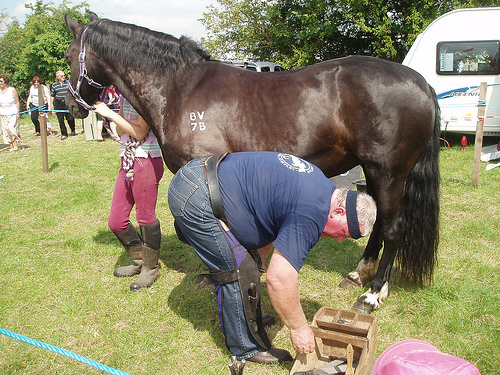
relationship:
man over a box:
[169, 150, 378, 365] [292, 305, 379, 374]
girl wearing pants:
[91, 90, 166, 290] [109, 154, 165, 232]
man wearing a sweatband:
[169, 150, 378, 365] [345, 189, 362, 241]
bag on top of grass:
[375, 341, 484, 374] [1, 112, 499, 374]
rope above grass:
[435, 82, 499, 107] [1, 112, 499, 374]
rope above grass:
[0, 105, 72, 116] [1, 112, 499, 374]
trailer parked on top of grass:
[394, 8, 500, 143] [1, 112, 499, 374]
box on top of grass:
[292, 305, 379, 374] [1, 112, 499, 374]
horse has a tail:
[64, 9, 442, 312] [391, 83, 439, 290]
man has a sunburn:
[169, 150, 378, 365] [320, 218, 365, 242]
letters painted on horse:
[188, 110, 209, 134] [64, 9, 442, 312]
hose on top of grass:
[0, 324, 133, 374] [1, 112, 499, 374]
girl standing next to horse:
[91, 90, 166, 290] [64, 9, 442, 312]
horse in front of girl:
[64, 9, 442, 312] [91, 90, 166, 290]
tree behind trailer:
[196, 1, 499, 73] [394, 8, 500, 143]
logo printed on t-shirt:
[277, 150, 314, 174] [219, 150, 335, 272]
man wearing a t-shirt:
[169, 150, 378, 365] [219, 150, 335, 272]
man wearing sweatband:
[169, 150, 378, 365] [345, 189, 362, 241]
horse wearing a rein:
[64, 9, 442, 312] [65, 21, 106, 115]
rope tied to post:
[435, 82, 499, 107] [473, 79, 489, 188]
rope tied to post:
[0, 105, 72, 116] [37, 83, 53, 173]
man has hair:
[169, 150, 378, 365] [338, 187, 377, 238]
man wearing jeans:
[169, 150, 378, 365] [166, 157, 267, 360]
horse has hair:
[64, 9, 442, 312] [78, 19, 208, 77]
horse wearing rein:
[64, 9, 442, 312] [65, 21, 106, 115]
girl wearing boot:
[91, 90, 166, 290] [112, 222, 146, 278]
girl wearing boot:
[91, 90, 166, 290] [128, 218, 161, 297]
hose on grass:
[0, 324, 133, 374] [1, 112, 499, 374]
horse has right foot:
[64, 9, 442, 312] [341, 206, 385, 290]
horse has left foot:
[64, 9, 442, 312] [352, 239, 400, 313]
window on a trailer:
[436, 39, 500, 78] [394, 8, 500, 143]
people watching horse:
[0, 68, 105, 152] [64, 9, 442, 312]